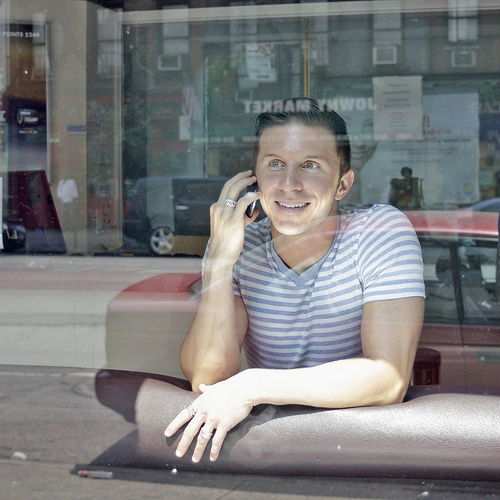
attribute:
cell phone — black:
[233, 166, 265, 223]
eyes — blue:
[260, 156, 319, 174]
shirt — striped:
[239, 221, 405, 353]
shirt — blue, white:
[245, 249, 393, 352]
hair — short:
[338, 118, 350, 149]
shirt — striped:
[244, 206, 419, 378]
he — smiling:
[177, 89, 393, 429]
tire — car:
[143, 225, 190, 258]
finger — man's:
[223, 165, 243, 195]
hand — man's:
[167, 390, 281, 452]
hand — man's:
[195, 172, 242, 302]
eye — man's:
[261, 155, 288, 177]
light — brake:
[123, 201, 133, 222]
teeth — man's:
[275, 195, 322, 218]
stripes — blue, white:
[261, 280, 315, 369]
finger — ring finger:
[224, 174, 255, 210]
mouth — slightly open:
[271, 198, 309, 210]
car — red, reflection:
[96, 212, 497, 429]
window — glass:
[2, 2, 497, 498]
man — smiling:
[163, 97, 424, 459]